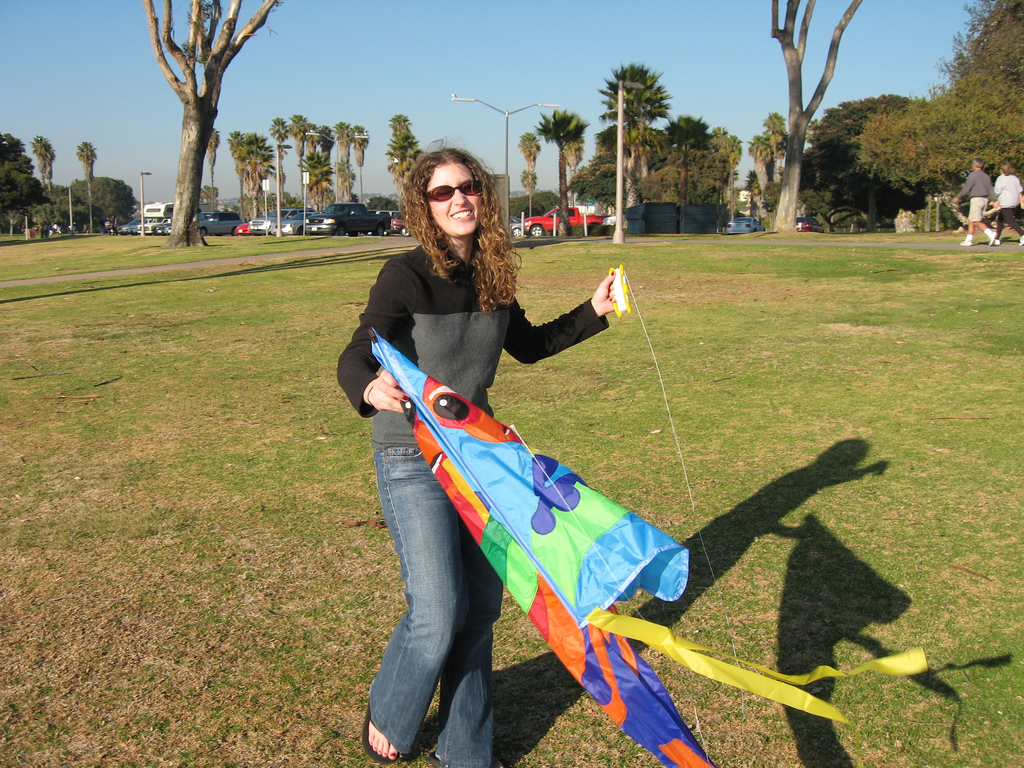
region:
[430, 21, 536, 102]
a view of sky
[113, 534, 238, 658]
a view of grass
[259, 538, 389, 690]
a view of trees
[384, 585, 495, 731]
a view of jeans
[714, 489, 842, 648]
a view of shadow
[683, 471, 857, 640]
shadow on the grass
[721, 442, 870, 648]
shadow of the girl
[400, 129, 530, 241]
a view of glases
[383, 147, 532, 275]
the head of a woman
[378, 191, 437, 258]
the hair of a woman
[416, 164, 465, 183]
the forehead of a woman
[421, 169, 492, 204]
the glasses of a woman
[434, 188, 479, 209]
the nose of a woman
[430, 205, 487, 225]
the mouth of a woman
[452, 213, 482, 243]
the chin of a woman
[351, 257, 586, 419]
the jacket of a woman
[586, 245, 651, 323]
the left hand of a woman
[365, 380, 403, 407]
the right hand of a woman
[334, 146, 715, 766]
girl holding a colorful kite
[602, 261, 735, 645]
yellow spool for the kite line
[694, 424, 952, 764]
shadow of the woman on the grass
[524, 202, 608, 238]
red pick up truck parked in a parking space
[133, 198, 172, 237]
white camper parked in a space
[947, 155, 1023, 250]
man wearing khaki shorts walking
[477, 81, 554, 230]
street lights in the parking lot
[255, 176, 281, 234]
parking information signs in the lot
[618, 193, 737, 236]
large trash bins on the parking lot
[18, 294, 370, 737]
grass next to the woman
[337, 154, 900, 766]
a woman holding a kite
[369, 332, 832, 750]
a colorful kite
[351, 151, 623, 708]
a woman in a black and grey sweater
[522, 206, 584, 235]
a red truck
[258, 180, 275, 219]
a white street sign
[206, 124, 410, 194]
trees behind the cars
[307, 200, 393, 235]
a black truck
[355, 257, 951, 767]
colorful kite with tail ribbons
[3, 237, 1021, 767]
water defficient lawn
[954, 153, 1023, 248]
cople enjoying a walk on a sunny day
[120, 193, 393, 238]
vehicles filling the parking lot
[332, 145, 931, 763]
woman flying a kite in the park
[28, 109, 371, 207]
towering healthy palm trees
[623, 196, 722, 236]
large city trash bins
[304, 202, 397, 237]
Ford F-150 pickup truck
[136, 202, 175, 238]
camping travel trailer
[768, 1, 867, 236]
Very tall dead tree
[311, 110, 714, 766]
woman holding kite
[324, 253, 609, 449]
gray and black jacket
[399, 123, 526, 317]
curly brown hair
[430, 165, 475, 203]
brown plastic sunglasses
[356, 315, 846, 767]
colorful patterned kit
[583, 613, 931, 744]
yellow waving kite banner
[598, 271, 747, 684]
white kite string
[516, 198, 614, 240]
red pickup truck in background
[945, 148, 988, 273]
man wearing khaki shorts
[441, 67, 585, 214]
gray metal light pole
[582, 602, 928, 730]
yellow tail attached to kite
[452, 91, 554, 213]
streetlight behind woman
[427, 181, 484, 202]
woman wearing brown sunglasses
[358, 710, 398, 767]
flip flop worn on foot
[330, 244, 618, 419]
black and gray sweater